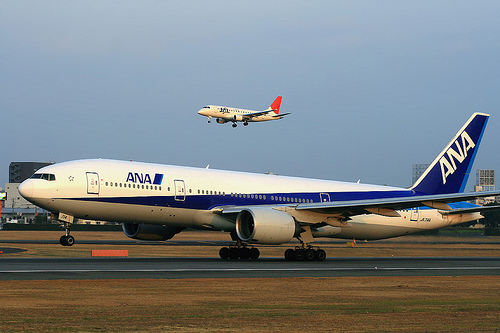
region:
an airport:
[7, 87, 498, 321]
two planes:
[17, 87, 499, 279]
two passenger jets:
[15, 87, 495, 275]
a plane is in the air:
[188, 90, 304, 137]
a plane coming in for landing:
[194, 86, 302, 136]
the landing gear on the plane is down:
[193, 92, 292, 137]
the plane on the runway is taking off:
[8, 110, 495, 285]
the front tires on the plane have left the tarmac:
[5, 107, 499, 292]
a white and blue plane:
[15, 110, 499, 304]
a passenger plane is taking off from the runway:
[8, 109, 495, 285]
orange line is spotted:
[99, 248, 106, 253]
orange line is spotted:
[116, 248, 121, 265]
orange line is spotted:
[110, 252, 122, 262]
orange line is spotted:
[104, 248, 115, 259]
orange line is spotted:
[105, 249, 120, 256]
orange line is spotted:
[103, 247, 108, 253]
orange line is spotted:
[115, 250, 126, 260]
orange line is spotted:
[105, 245, 115, 252]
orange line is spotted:
[110, 247, 122, 253]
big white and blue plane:
[19, 82, 493, 252]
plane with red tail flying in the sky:
[183, 82, 299, 139]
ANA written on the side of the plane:
[118, 157, 171, 192]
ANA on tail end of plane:
[420, 94, 497, 203]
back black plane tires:
[211, 237, 343, 271]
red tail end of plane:
[266, 89, 289, 121]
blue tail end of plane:
[415, 92, 487, 214]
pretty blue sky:
[30, 10, 458, 95]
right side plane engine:
[222, 190, 297, 245]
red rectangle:
[84, 240, 140, 266]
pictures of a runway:
[7, 11, 482, 302]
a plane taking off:
[182, 75, 298, 140]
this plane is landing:
[11, 105, 498, 288]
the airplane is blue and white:
[25, 109, 499, 264]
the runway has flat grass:
[6, 237, 495, 329]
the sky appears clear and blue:
[6, 12, 498, 185]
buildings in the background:
[413, 136, 498, 241]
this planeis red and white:
[191, 78, 303, 124]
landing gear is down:
[31, 199, 338, 281]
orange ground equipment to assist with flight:
[66, 226, 160, 277]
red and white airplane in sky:
[195, 81, 295, 131]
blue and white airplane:
[10, 113, 482, 254]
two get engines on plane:
[116, 208, 407, 250]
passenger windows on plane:
[102, 173, 437, 220]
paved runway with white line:
[12, 255, 498, 290]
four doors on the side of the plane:
[80, 170, 431, 222]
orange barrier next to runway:
[86, 244, 169, 273]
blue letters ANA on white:
[116, 168, 179, 190]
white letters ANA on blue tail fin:
[413, 105, 494, 203]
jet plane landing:
[182, 91, 328, 136]